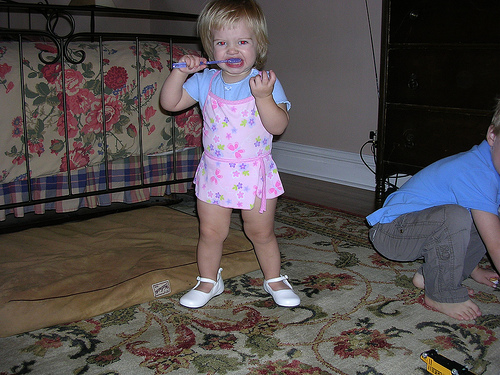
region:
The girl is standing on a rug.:
[158, 0, 370, 351]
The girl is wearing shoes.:
[151, 1, 318, 333]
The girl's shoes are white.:
[154, 0, 331, 319]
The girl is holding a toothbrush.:
[158, 0, 300, 152]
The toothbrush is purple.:
[155, 0, 292, 137]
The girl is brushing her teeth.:
[154, 0, 310, 142]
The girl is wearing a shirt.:
[153, 0, 300, 141]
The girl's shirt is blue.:
[153, 1, 303, 151]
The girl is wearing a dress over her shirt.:
[150, 0, 312, 312]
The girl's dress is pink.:
[153, 0, 326, 316]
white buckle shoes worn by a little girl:
[177, 268, 312, 310]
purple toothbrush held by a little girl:
[170, 54, 251, 69]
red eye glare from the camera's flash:
[212, 33, 252, 48]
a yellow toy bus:
[414, 343, 484, 373]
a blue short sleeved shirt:
[365, 136, 499, 226]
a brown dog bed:
[6, 205, 178, 312]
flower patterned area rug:
[85, 319, 392, 373]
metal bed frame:
[11, 1, 166, 44]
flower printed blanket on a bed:
[25, 56, 67, 170]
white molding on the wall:
[287, 140, 365, 185]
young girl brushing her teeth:
[159, 4, 301, 310]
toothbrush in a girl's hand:
[171, 54, 243, 74]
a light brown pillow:
[0, 210, 257, 345]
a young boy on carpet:
[365, 99, 499, 319]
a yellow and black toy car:
[418, 348, 470, 373]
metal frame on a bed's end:
[0, 0, 202, 213]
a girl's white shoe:
[177, 269, 225, 309]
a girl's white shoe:
[262, 273, 299, 308]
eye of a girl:
[214, 38, 226, 47]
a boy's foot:
[421, 288, 482, 319]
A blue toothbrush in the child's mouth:
[177, 52, 255, 77]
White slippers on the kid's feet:
[182, 271, 299, 316]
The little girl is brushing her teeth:
[153, 14, 306, 322]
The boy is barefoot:
[398, 260, 487, 320]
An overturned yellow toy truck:
[425, 343, 468, 374]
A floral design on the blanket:
[2, 37, 207, 164]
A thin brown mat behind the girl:
[5, 209, 237, 304]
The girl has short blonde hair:
[200, 8, 274, 62]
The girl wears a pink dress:
[190, 91, 282, 201]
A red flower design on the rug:
[328, 316, 401, 365]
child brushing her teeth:
[171, 5, 311, 308]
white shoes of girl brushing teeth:
[177, 264, 298, 315]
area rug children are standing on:
[41, 198, 496, 374]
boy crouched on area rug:
[365, 98, 499, 353]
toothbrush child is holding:
[170, 55, 246, 72]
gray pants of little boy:
[375, 197, 480, 292]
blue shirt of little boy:
[367, 159, 487, 219]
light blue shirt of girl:
[190, 72, 291, 101]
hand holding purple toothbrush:
[172, 50, 214, 78]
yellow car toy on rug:
[412, 333, 456, 374]